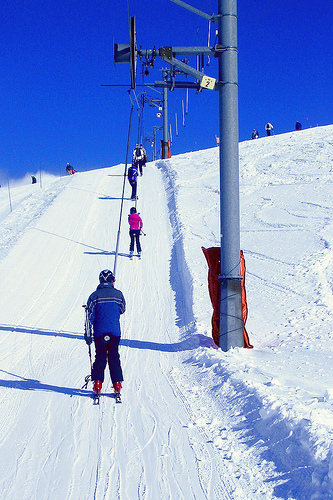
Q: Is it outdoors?
A: Yes, it is outdoors.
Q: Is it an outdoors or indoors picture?
A: It is outdoors.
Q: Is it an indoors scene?
A: No, it is outdoors.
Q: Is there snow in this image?
A: Yes, there is snow.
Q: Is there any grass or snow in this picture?
A: Yes, there is snow.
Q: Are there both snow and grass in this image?
A: No, there is snow but no grass.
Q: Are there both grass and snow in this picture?
A: No, there is snow but no grass.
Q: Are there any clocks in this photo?
A: No, there are no clocks.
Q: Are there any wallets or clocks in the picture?
A: No, there are no clocks or wallets.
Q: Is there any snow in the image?
A: Yes, there is snow.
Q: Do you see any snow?
A: Yes, there is snow.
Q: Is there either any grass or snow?
A: Yes, there is snow.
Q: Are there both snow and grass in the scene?
A: No, there is snow but no grass.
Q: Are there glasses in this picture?
A: No, there are no glasses.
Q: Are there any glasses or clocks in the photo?
A: No, there are no glasses or clocks.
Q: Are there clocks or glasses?
A: No, there are no glasses or clocks.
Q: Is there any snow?
A: Yes, there is snow.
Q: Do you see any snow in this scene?
A: Yes, there is snow.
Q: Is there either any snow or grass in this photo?
A: Yes, there is snow.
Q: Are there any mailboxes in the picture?
A: No, there are no mailboxes.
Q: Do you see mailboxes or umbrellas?
A: No, there are no mailboxes or umbrellas.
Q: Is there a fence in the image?
A: No, there are no fences.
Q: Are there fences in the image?
A: No, there are no fences.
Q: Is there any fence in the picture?
A: No, there are no fences.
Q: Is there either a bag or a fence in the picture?
A: No, there are no fences or bags.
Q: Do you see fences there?
A: No, there are no fences.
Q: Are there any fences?
A: No, there are no fences.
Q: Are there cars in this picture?
A: No, there are no cars.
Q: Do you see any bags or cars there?
A: No, there are no cars or bags.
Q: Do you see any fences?
A: No, there are no fences.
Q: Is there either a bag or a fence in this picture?
A: No, there are no fences or bags.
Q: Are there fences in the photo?
A: No, there are no fences.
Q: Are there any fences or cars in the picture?
A: No, there are no fences or cars.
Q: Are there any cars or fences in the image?
A: No, there are no fences or cars.